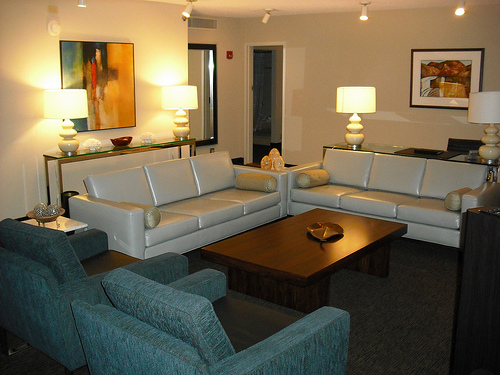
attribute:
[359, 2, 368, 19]
light — lit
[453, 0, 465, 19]
light — lit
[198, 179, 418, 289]
table — wooden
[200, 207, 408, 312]
table — wooden, brown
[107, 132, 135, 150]
bowl — red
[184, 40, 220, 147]
mirror — black trimmed, hung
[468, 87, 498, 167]
lamp — white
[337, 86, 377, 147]
lamp — white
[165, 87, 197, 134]
lamp — white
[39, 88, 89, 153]
lamp — white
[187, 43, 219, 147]
mirror — clear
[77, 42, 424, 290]
area — living room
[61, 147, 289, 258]
leather sofa — silver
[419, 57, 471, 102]
art piece — black framed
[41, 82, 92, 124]
light — glowing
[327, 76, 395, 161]
lamp — lit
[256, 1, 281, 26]
light — glowing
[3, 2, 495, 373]
living room — white and blue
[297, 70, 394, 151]
light room — glowing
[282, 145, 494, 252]
couch — white, three seated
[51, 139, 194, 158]
stand — brown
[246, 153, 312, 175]
table — brown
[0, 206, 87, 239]
table — brown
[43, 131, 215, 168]
table — brown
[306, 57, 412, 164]
light — glowing